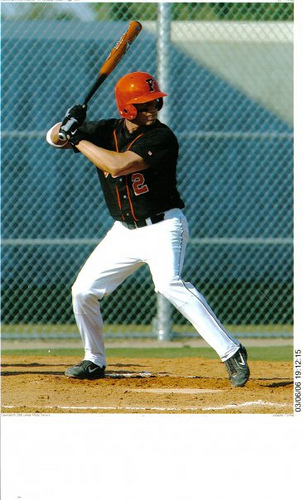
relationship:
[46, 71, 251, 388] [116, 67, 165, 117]
baseball player wearing helmet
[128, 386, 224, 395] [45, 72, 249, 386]
base plate below batter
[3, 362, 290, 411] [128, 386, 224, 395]
dirt near base plate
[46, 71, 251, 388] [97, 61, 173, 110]
baseball player wearing helmet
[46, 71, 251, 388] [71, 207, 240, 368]
baseball player wearing pants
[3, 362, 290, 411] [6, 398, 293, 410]
dirt with stripe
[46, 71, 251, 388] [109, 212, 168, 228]
baseball player wearing belt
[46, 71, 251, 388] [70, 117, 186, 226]
baseball player wearing black jersey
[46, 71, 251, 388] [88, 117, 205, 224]
baseball player wearing shirt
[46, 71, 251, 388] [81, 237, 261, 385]
baseball player wearing pants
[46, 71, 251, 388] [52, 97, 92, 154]
baseball player wearing gloves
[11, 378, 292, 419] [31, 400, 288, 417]
clay with lines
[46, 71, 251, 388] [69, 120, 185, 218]
baseball player wearing a uniform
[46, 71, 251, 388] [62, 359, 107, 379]
baseball player wearing shoe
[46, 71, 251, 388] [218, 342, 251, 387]
baseball player wearing shoe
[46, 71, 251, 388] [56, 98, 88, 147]
baseball player wearing gloves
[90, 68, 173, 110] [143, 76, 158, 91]
helmet with letter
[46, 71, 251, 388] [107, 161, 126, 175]
baseball player has elbow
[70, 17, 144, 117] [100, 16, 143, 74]
baseball bat has rounded end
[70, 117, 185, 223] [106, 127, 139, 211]
black jersey has stripe